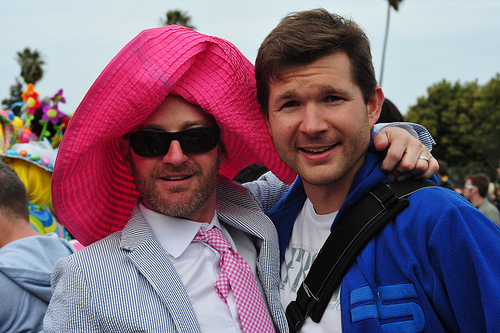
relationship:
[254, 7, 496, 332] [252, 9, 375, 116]
man has hair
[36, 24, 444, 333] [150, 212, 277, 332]
man wearing shirt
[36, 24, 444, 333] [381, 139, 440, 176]
man wearing ring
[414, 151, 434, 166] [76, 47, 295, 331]
ring on man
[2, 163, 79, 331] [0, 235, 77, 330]
man wearing gray hoodie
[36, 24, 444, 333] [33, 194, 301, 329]
man wearing jacket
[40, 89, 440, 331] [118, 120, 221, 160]
man in sunglasses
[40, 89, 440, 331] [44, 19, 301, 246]
man in hat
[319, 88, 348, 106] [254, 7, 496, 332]
eye of man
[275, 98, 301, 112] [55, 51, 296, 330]
eye of man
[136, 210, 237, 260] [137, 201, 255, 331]
collar on shirt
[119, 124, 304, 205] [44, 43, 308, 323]
sunglasses on man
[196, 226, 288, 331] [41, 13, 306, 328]
tie of man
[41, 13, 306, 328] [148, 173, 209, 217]
man with beard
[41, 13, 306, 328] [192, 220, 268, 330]
man wearing tie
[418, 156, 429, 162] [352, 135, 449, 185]
ring on finger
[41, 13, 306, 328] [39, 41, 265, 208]
man in hat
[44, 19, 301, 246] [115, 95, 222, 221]
hat on head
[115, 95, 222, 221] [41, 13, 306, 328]
head of man